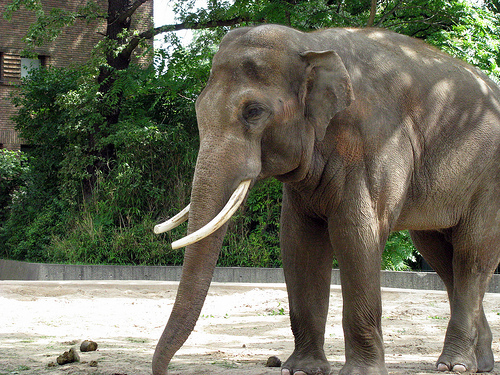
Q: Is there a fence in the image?
A: No, there are no fences.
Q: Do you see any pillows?
A: No, there are no pillows.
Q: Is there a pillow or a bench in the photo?
A: No, there are no pillows or benches.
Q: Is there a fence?
A: No, there are no fences.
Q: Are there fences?
A: No, there are no fences.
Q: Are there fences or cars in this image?
A: No, there are no fences or cars.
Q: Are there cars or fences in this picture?
A: No, there are no fences or cars.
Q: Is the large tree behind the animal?
A: Yes, the tree is behind the animal.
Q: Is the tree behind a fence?
A: No, the tree is behind the animal.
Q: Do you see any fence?
A: No, there are no fences.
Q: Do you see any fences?
A: No, there are no fences.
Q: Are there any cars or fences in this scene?
A: No, there are no fences or cars.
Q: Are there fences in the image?
A: No, there are no fences.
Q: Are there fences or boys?
A: No, there are no fences or boys.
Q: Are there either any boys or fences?
A: No, there are no fences or boys.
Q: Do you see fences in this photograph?
A: No, there are no fences.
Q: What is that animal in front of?
A: The animal is in front of the tree.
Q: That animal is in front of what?
A: The animal is in front of the tree.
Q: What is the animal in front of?
A: The animal is in front of the tree.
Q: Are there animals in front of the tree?
A: Yes, there is an animal in front of the tree.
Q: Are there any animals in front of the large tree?
A: Yes, there is an animal in front of the tree.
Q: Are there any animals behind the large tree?
A: No, the animal is in front of the tree.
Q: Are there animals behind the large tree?
A: No, the animal is in front of the tree.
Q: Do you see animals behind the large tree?
A: No, the animal is in front of the tree.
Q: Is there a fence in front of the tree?
A: No, there is an animal in front of the tree.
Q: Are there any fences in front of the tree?
A: No, there is an animal in front of the tree.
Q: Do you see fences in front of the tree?
A: No, there is an animal in front of the tree.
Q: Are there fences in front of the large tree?
A: No, there is an animal in front of the tree.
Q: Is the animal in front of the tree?
A: Yes, the animal is in front of the tree.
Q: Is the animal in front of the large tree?
A: Yes, the animal is in front of the tree.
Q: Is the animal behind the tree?
A: No, the animal is in front of the tree.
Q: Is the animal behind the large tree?
A: No, the animal is in front of the tree.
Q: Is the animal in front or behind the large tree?
A: The animal is in front of the tree.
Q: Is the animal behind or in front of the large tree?
A: The animal is in front of the tree.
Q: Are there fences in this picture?
A: No, there are no fences.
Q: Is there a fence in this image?
A: No, there are no fences.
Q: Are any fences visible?
A: No, there are no fences.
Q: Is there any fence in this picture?
A: No, there are no fences.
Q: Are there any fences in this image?
A: No, there are no fences.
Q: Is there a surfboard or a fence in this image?
A: No, there are no fences or surfboards.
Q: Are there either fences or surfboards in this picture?
A: No, there are no fences or surfboards.